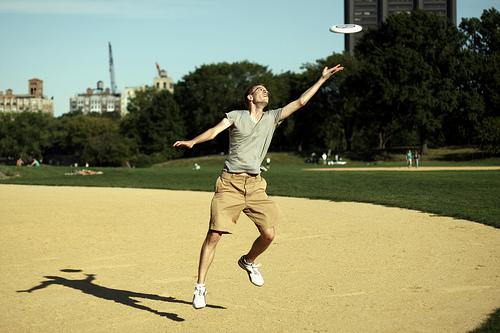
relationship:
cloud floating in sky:
[8, 0, 106, 22] [0, 2, 337, 65]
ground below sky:
[11, 170, 488, 329] [0, 2, 337, 65]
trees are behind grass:
[0, 3, 499, 171] [19, 162, 499, 206]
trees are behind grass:
[3, 115, 167, 166] [19, 162, 499, 206]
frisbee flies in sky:
[325, 21, 370, 42] [0, 2, 337, 65]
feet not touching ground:
[189, 284, 211, 314] [11, 170, 488, 329]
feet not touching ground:
[237, 258, 266, 289] [11, 170, 488, 329]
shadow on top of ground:
[17, 266, 228, 327] [11, 170, 488, 329]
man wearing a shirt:
[172, 63, 345, 312] [226, 110, 283, 177]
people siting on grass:
[17, 155, 115, 182] [19, 162, 499, 206]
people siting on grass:
[26, 158, 40, 168] [19, 162, 499, 206]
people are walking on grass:
[406, 148, 424, 171] [19, 162, 499, 206]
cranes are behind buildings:
[107, 36, 121, 98] [0, 73, 177, 117]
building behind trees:
[344, 1, 458, 160] [0, 3, 499, 171]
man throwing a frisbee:
[172, 63, 345, 312] [325, 21, 370, 42]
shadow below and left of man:
[17, 266, 228, 327] [172, 63, 345, 312]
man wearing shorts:
[172, 63, 345, 312] [205, 170, 287, 241]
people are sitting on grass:
[17, 155, 115, 182] [19, 162, 499, 206]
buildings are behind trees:
[0, 73, 177, 117] [3, 115, 167, 166]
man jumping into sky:
[172, 63, 345, 312] [0, 2, 337, 65]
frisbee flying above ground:
[325, 21, 370, 42] [11, 170, 488, 329]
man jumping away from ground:
[172, 63, 345, 312] [11, 170, 488, 329]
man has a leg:
[172, 63, 345, 312] [192, 201, 232, 295]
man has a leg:
[172, 63, 345, 312] [249, 193, 278, 262]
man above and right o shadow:
[172, 63, 345, 312] [17, 266, 228, 327]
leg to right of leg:
[192, 201, 232, 295] [249, 193, 278, 262]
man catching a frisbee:
[172, 63, 345, 312] [325, 21, 370, 42]